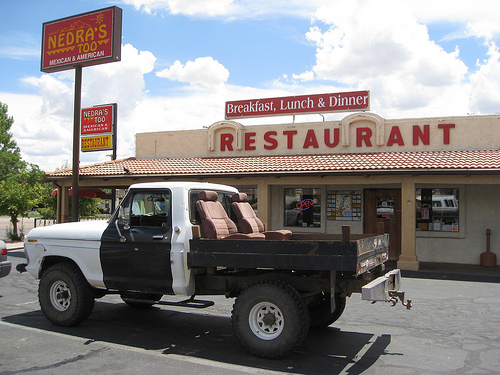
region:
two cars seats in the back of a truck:
[166, 182, 291, 292]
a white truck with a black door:
[43, 165, 207, 317]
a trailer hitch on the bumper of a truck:
[373, 277, 430, 323]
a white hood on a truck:
[28, 197, 117, 275]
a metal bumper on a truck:
[357, 262, 417, 321]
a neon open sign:
[291, 192, 326, 216]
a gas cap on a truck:
[165, 217, 184, 247]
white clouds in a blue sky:
[238, 29, 445, 75]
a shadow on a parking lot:
[310, 329, 415, 374]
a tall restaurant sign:
[39, 6, 126, 173]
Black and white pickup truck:
[23, 181, 413, 357]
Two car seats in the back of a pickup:
[194, 188, 292, 245]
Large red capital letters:
[210, 123, 455, 152]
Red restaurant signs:
[219, 96, 456, 150]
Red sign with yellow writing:
[37, 6, 122, 73]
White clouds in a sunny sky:
[0, 0, 497, 177]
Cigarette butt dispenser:
[477, 227, 497, 268]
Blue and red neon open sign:
[291, 196, 316, 213]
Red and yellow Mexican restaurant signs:
[79, 103, 119, 160]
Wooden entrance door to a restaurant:
[361, 186, 404, 262]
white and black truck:
[16, 180, 413, 359]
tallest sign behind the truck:
[37, 6, 123, 73]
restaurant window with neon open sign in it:
[286, 189, 323, 229]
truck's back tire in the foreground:
[232, 283, 306, 358]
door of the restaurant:
[362, 187, 400, 261]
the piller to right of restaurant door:
[397, 181, 421, 271]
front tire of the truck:
[38, 263, 95, 329]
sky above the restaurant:
[2, 2, 497, 131]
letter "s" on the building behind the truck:
[262, 129, 278, 151]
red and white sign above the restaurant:
[217, 89, 370, 119]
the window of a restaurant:
[414, 189, 459, 233]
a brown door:
[367, 190, 400, 257]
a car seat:
[199, 190, 265, 242]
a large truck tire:
[233, 283, 310, 355]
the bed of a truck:
[185, 222, 390, 285]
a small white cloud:
[153, 56, 233, 83]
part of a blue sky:
[2, 0, 95, 16]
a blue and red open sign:
[292, 195, 316, 212]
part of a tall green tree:
[0, 106, 38, 211]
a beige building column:
[399, 183, 419, 263]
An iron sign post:
[71, 68, 82, 214]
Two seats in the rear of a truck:
[195, 188, 258, 238]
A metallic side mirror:
[115, 203, 130, 222]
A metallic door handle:
[150, 233, 165, 240]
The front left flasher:
[29, 239, 36, 243]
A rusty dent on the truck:
[36, 243, 46, 250]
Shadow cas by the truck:
[118, 306, 173, 337]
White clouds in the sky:
[151, 99, 204, 122]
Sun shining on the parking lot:
[427, 295, 498, 350]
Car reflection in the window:
[435, 193, 455, 213]